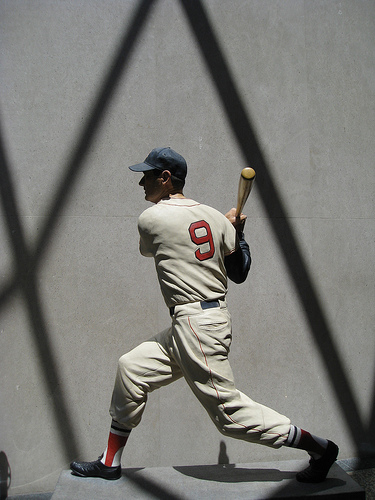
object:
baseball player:
[66, 144, 339, 484]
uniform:
[111, 191, 300, 452]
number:
[187, 217, 215, 263]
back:
[146, 193, 225, 302]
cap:
[129, 147, 187, 183]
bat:
[235, 166, 254, 224]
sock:
[99, 423, 130, 467]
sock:
[285, 423, 330, 461]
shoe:
[294, 438, 338, 486]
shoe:
[68, 449, 125, 481]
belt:
[169, 294, 227, 316]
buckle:
[173, 301, 204, 316]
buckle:
[217, 297, 228, 308]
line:
[105, 428, 119, 464]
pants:
[110, 305, 301, 448]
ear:
[162, 169, 172, 185]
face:
[138, 170, 161, 201]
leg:
[101, 330, 182, 466]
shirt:
[136, 189, 238, 306]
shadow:
[122, 460, 171, 499]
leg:
[198, 354, 325, 451]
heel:
[324, 437, 340, 457]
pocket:
[201, 320, 232, 356]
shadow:
[4, 1, 369, 491]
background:
[23, 10, 371, 500]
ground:
[10, 271, 375, 497]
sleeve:
[217, 209, 241, 259]